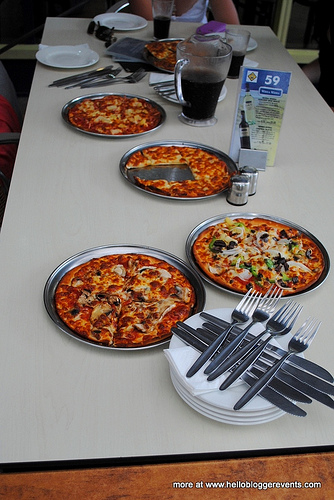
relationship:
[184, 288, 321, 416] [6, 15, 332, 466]
forks on table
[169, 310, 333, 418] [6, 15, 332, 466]
knives on table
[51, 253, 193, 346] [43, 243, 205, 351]
pizza in pan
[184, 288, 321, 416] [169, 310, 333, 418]
forks and knives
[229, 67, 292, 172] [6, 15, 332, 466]
menu on table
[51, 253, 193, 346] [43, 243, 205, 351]
pizza on plate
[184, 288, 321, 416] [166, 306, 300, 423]
forks on white plates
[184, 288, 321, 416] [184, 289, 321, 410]
forks are made of metal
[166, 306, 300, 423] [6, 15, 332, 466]
white plates on table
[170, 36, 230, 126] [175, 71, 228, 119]
pitcher of juice